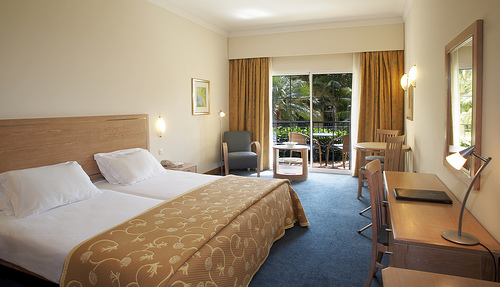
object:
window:
[271, 72, 353, 176]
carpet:
[287, 255, 360, 274]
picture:
[197, 86, 207, 106]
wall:
[0, 1, 30, 92]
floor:
[265, 238, 350, 277]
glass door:
[273, 73, 353, 169]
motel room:
[0, 0, 499, 287]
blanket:
[58, 175, 310, 287]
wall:
[166, 25, 226, 51]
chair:
[357, 158, 388, 286]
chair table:
[353, 141, 411, 176]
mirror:
[447, 34, 473, 152]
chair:
[221, 131, 261, 177]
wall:
[251, 22, 402, 42]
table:
[272, 145, 308, 180]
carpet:
[307, 193, 354, 209]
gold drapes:
[356, 49, 403, 142]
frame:
[191, 78, 211, 116]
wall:
[191, 121, 225, 146]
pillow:
[0, 160, 103, 219]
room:
[0, 0, 500, 287]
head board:
[0, 114, 151, 184]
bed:
[0, 114, 310, 287]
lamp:
[154, 116, 167, 156]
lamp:
[440, 145, 493, 246]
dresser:
[382, 170, 500, 281]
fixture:
[400, 64, 416, 122]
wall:
[405, 23, 446, 173]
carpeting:
[301, 177, 339, 187]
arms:
[222, 142, 229, 176]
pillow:
[93, 148, 168, 186]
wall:
[152, 82, 173, 119]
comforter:
[0, 148, 310, 286]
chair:
[357, 135, 406, 199]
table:
[382, 170, 499, 254]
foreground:
[0, 151, 500, 287]